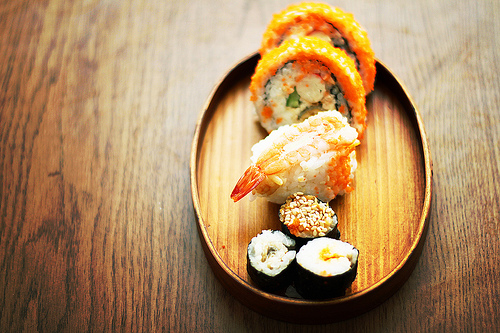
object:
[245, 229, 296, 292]
sushi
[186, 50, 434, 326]
plate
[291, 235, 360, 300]
sushi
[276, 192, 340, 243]
sushi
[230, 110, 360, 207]
sushi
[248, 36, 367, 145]
sushi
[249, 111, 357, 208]
rice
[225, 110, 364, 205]
middle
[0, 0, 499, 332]
table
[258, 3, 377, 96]
sushi